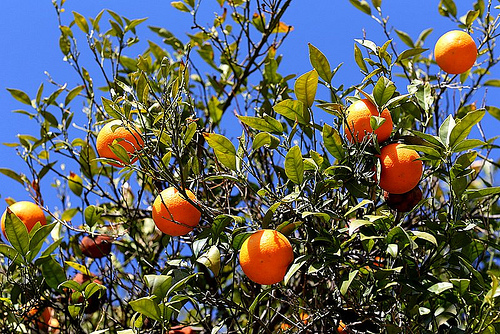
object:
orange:
[377, 141, 421, 195]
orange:
[345, 98, 394, 143]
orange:
[0, 199, 49, 242]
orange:
[152, 185, 204, 237]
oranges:
[433, 28, 475, 74]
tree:
[1, 0, 498, 334]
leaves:
[200, 131, 235, 157]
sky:
[2, 1, 458, 334]